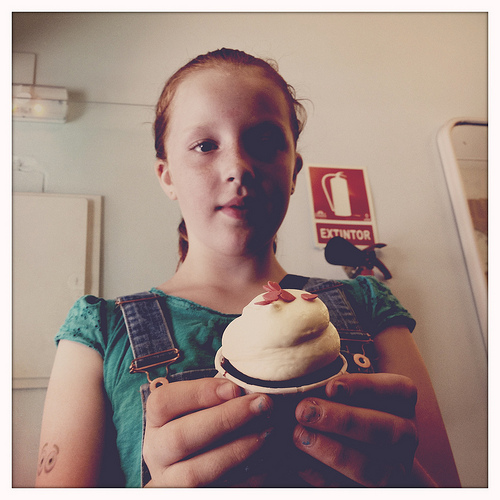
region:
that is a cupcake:
[204, 298, 333, 391]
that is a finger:
[151, 366, 239, 408]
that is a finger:
[170, 398, 257, 431]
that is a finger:
[188, 428, 271, 473]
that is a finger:
[331, 379, 426, 402]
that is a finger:
[299, 398, 432, 447]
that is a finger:
[290, 421, 329, 463]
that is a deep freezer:
[19, 235, 97, 284]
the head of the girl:
[158, 43, 290, 280]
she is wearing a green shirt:
[190, 314, 208, 348]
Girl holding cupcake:
[35, 49, 460, 487]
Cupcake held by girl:
[212, 282, 345, 459]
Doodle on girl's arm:
[37, 441, 61, 474]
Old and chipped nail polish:
[298, 401, 318, 421]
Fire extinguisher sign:
[306, 165, 373, 246]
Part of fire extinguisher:
[321, 236, 389, 277]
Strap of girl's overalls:
[115, 295, 176, 386]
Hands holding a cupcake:
[140, 372, 415, 479]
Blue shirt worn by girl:
[70, 295, 221, 377]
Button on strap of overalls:
[351, 353, 370, 369]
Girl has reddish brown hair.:
[154, 43, 309, 88]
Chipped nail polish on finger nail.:
[298, 400, 327, 450]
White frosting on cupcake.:
[237, 314, 299, 358]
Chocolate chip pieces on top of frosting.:
[254, 273, 331, 321]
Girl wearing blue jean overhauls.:
[126, 286, 398, 413]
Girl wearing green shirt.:
[174, 302, 206, 336]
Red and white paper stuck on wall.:
[319, 165, 390, 272]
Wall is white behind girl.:
[128, 208, 161, 253]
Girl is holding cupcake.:
[174, 347, 362, 462]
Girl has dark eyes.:
[191, 133, 230, 170]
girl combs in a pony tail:
[19, 33, 470, 485]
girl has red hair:
[100, 32, 370, 346]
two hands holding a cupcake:
[134, 268, 430, 486]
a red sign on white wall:
[305, 155, 387, 259]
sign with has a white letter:
[301, 154, 383, 246]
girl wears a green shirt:
[46, 37, 462, 477]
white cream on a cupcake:
[209, 270, 356, 402]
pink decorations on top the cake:
[243, 268, 324, 319]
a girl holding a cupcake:
[94, 45, 439, 497]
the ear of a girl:
[149, 155, 179, 200]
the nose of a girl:
[219, 140, 255, 187]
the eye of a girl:
[184, 130, 223, 157]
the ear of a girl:
[287, 145, 303, 197]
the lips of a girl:
[213, 190, 270, 222]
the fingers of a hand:
[137, 376, 276, 487]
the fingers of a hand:
[291, 370, 423, 491]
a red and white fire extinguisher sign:
[305, 157, 396, 252]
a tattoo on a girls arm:
[29, 432, 71, 482]